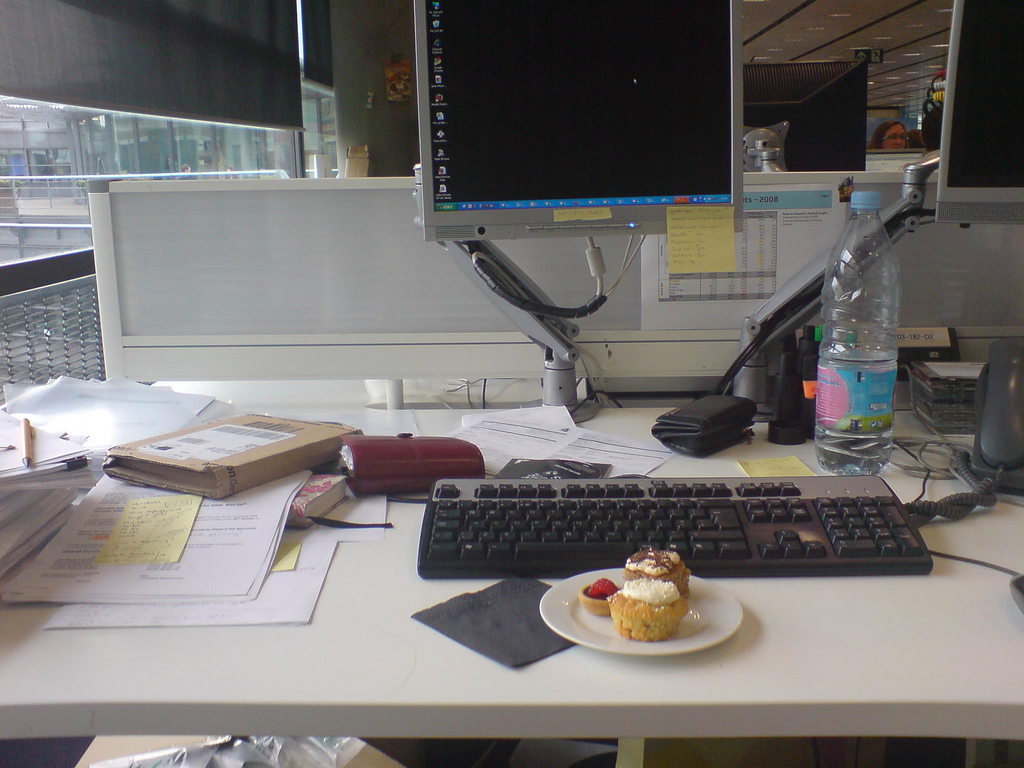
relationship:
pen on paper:
[12, 415, 45, 474] [2, 398, 102, 580]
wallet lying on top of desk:
[647, 389, 760, 457] [4, 396, 981, 751]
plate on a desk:
[501, 539, 756, 673] [4, 396, 981, 751]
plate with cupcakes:
[539, 568, 745, 657] [568, 532, 692, 630]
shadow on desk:
[2, 590, 54, 660] [4, 396, 981, 751]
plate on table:
[539, 568, 745, 657] [4, 400, 977, 736]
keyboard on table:
[419, 474, 945, 581] [4, 400, 977, 736]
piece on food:
[583, 579, 614, 595] [587, 575, 624, 612]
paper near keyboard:
[23, 465, 332, 632] [423, 465, 962, 587]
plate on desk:
[539, 568, 745, 657] [68, 431, 998, 745]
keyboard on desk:
[417, 474, 934, 579] [69, 446, 964, 710]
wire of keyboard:
[905, 528, 1003, 604] [410, 441, 946, 608]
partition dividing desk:
[159, 171, 987, 420] [0, 380, 1024, 742]